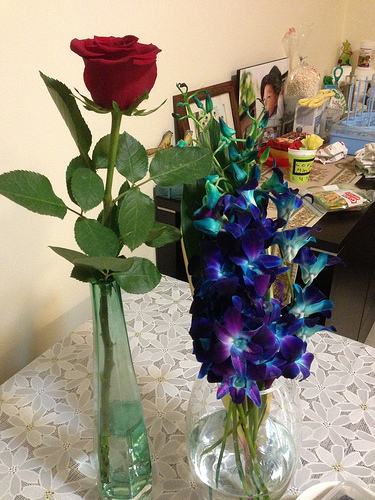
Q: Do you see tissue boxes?
A: No, there are no tissue boxes.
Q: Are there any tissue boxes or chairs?
A: No, there are no tissue boxes or chairs.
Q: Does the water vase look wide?
A: Yes, the vase is wide.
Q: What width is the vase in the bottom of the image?
A: The vase is wide.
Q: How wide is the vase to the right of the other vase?
A: The vase is wide.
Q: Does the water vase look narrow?
A: No, the vase is wide.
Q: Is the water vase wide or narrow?
A: The vase is wide.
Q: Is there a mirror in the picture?
A: No, there are no mirrors.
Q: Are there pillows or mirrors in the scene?
A: No, there are no mirrors or pillows.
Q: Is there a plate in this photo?
A: No, there are no plates.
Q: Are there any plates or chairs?
A: No, there are no plates or chairs.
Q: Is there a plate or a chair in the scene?
A: No, there are no plates or chairs.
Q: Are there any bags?
A: Yes, there is a bag.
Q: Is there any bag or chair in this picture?
A: Yes, there is a bag.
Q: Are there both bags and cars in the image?
A: No, there is a bag but no cars.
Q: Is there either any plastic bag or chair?
A: Yes, there is a plastic bag.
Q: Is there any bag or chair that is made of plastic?
A: Yes, the bag is made of plastic.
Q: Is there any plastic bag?
A: Yes, there is a bag that is made of plastic.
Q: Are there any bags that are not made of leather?
A: Yes, there is a bag that is made of plastic.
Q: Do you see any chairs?
A: No, there are no chairs.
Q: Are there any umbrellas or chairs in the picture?
A: No, there are no chairs or umbrellas.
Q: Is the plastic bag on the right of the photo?
A: Yes, the bag is on the right of the image.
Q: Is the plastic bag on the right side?
A: Yes, the bag is on the right of the image.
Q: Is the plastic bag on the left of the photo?
A: No, the bag is on the right of the image.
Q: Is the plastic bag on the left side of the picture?
A: No, the bag is on the right of the image.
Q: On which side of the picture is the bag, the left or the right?
A: The bag is on the right of the image.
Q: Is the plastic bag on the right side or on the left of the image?
A: The bag is on the right of the image.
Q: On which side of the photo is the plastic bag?
A: The bag is on the right of the image.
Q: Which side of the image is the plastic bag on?
A: The bag is on the right of the image.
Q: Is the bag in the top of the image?
A: Yes, the bag is in the top of the image.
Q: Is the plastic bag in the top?
A: Yes, the bag is in the top of the image.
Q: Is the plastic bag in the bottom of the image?
A: No, the bag is in the top of the image.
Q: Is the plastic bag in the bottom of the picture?
A: No, the bag is in the top of the image.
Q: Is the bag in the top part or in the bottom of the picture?
A: The bag is in the top of the image.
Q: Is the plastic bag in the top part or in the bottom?
A: The bag is in the top of the image.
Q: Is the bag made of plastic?
A: Yes, the bag is made of plastic.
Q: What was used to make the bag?
A: The bag is made of plastic.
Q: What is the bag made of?
A: The bag is made of plastic.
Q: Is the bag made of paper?
A: No, the bag is made of plastic.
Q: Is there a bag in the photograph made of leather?
A: No, there is a bag but it is made of plastic.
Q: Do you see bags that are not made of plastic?
A: No, there is a bag but it is made of plastic.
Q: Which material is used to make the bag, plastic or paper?
A: The bag is made of plastic.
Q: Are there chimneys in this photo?
A: No, there are no chimneys.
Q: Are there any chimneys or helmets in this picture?
A: No, there are no chimneys or helmets.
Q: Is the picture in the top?
A: Yes, the picture is in the top of the image.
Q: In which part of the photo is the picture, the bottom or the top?
A: The picture is in the top of the image.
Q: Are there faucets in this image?
A: No, there are no faucets.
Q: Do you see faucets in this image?
A: No, there are no faucets.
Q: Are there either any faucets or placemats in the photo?
A: No, there are no faucets or placemats.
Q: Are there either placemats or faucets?
A: No, there are no faucets or placemats.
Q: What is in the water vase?
A: The flowers are in the vase.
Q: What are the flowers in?
A: The flowers are in the vase.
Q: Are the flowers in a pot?
A: No, the flowers are in the vase.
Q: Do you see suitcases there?
A: No, there are no suitcases.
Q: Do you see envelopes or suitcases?
A: No, there are no suitcases or envelopes.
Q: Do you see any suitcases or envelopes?
A: No, there are no suitcases or envelopes.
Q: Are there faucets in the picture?
A: No, there are no faucets.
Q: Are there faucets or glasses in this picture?
A: No, there are no faucets or glasses.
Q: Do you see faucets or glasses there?
A: No, there are no faucets or glasses.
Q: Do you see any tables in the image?
A: Yes, there is a table.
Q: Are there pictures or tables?
A: Yes, there is a table.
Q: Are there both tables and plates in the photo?
A: No, there is a table but no plates.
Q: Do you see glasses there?
A: No, there are no glasses.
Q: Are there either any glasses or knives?
A: No, there are no glasses or knives.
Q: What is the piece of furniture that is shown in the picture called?
A: The piece of furniture is a table.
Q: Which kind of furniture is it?
A: The piece of furniture is a table.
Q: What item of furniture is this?
A: This is a table.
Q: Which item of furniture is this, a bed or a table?
A: This is a table.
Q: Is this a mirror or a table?
A: This is a table.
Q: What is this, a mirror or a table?
A: This is a table.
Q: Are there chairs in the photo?
A: No, there are no chairs.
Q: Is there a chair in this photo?
A: No, there are no chairs.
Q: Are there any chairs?
A: No, there are no chairs.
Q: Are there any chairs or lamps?
A: No, there are no chairs or lamps.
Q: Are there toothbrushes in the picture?
A: No, there are no toothbrushes.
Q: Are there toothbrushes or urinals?
A: No, there are no toothbrushes or urinals.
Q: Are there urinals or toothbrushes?
A: No, there are no toothbrushes or urinals.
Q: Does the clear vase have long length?
A: Yes, the vase is long.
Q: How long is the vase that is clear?
A: The vase is long.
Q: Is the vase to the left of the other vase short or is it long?
A: The vase is long.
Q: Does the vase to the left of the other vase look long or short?
A: The vase is long.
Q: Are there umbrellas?
A: No, there are no umbrellas.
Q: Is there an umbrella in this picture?
A: No, there are no umbrellas.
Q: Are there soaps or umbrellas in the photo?
A: No, there are no umbrellas or soaps.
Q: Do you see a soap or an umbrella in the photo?
A: No, there are no umbrellas or soaps.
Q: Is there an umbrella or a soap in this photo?
A: No, there are no umbrellas or soaps.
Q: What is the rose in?
A: The rose is in the vase.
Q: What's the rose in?
A: The rose is in the vase.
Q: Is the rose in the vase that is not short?
A: Yes, the rose is in the vase.